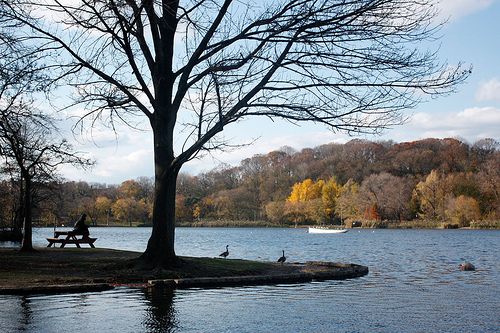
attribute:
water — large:
[102, 224, 499, 269]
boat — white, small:
[301, 225, 349, 235]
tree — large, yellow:
[3, 4, 468, 263]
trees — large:
[187, 141, 496, 230]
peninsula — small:
[184, 254, 372, 288]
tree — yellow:
[287, 176, 323, 200]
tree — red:
[364, 203, 383, 222]